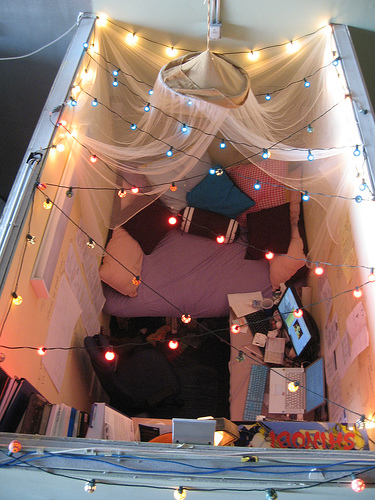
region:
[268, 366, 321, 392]
light on a cord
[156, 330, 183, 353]
light on a cord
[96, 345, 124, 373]
light on a cord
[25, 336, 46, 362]
light on a cord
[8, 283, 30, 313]
light on a cord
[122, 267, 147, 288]
light on a cord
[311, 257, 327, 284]
light on a cord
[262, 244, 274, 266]
light on a cord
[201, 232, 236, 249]
light on a cord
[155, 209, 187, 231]
light on a cord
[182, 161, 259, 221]
a blue pillow on a bed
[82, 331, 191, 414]
a dark grey office chair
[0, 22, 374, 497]
lights strung above a room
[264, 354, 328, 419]
a laptop on a desk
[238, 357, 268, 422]
a grey keyboard on a desk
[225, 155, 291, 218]
a pink and white checkered pillow on a bed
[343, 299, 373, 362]
a paper pinned to a wall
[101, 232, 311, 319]
a light purple sheet on a bed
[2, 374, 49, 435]
a binder on a shelf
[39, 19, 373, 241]
mosquito netting hug over the top of a room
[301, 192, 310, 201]
blue light on string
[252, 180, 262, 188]
blue light on string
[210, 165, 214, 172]
blue light on string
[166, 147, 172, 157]
blue light on string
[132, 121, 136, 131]
blue light on string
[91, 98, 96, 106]
blue light on string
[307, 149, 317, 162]
blue light on string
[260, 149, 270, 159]
blue light on string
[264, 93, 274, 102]
blue light on string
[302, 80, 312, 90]
blue light on string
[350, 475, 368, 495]
red light on string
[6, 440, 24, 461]
red light on string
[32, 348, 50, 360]
red light on string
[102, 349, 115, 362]
red light on string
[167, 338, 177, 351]
red light on string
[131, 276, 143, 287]
red light on string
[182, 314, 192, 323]
red light on string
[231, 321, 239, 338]
red light on string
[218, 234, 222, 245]
red light on string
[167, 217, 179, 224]
red light on string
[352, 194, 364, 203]
blue colored light bulb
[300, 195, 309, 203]
blue colored light bulb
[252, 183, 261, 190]
blue colored light bulb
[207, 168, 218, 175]
blue colored light bulb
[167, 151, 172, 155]
blue colored light bulb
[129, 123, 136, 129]
blue colored light bulb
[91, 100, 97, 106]
blue colored light bulb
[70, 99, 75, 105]
blue colored light bulb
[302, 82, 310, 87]
blue colored light bulb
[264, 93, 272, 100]
blue colored light bulb